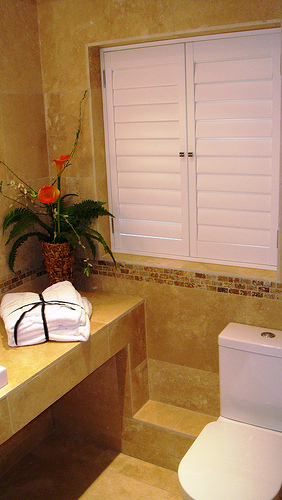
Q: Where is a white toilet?
A: On the wall.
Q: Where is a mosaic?
A: Brown tiled wall.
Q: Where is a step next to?
A: The toilet.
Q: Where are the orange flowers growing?
A: In a vase.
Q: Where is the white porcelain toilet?
A: In the bathroom.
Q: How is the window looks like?
A: Closed.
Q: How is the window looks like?
A: White.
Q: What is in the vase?
A: Flower.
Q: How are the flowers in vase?
A: Fresh.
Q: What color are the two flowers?
A: Orange.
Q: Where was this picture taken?
A: Bathroom.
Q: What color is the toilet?
A: White.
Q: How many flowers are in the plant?
A: Two.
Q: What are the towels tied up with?
A: A black ribbon.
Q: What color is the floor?
A: Light brown.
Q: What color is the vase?
A: Brown.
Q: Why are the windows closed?
A: For privacy.